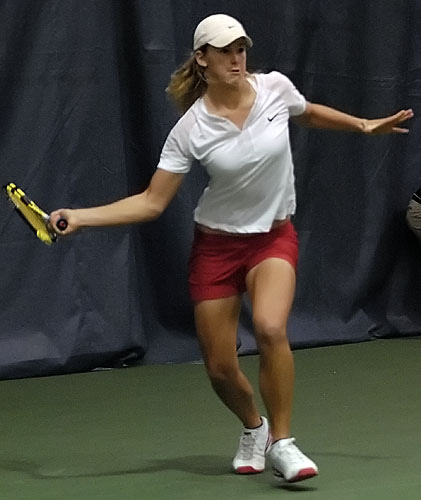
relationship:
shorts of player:
[188, 216, 299, 304] [134, 84, 318, 327]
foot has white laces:
[264, 433, 318, 484] [241, 435, 257, 455]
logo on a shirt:
[264, 112, 281, 123] [183, 104, 302, 223]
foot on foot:
[231, 415, 273, 475] [228, 413, 270, 475]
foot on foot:
[264, 433, 318, 484] [266, 435, 319, 482]